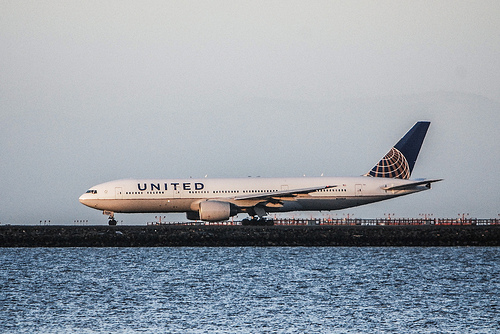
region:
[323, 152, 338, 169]
part of an ocean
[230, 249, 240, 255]
part of the sea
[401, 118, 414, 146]
edge of a plane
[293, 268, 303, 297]
part of a water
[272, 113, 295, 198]
part of a plane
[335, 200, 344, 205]
part of a plane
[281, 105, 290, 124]
part of a cloud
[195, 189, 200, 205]
part of a wheel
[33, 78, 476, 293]
plane next to the water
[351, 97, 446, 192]
tail of the plane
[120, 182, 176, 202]
windows on side of plane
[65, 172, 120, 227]
nose of the plane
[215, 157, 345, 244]
wing of the plane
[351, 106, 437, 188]
design on the tail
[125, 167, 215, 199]
word on side of plane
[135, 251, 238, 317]
water near the plane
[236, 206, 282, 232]
wheels on bottom of plane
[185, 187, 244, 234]
engine on side of plane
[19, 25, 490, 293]
this is a plane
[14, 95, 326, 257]
this is a runway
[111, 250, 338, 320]
this is a body of water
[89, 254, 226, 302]
the water is calm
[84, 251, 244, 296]
the water is blue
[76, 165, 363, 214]
this is a passenger plane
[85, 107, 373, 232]
this is a commercial flight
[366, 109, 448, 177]
the tail is blue and yellow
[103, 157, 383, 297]
the plane is gold and white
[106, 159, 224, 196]
the writing says "united"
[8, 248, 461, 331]
water in front of the airplane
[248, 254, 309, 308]
small waves in the water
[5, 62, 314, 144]
clouds in the sky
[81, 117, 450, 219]
an airplane on the runway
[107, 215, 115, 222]
a wheel on the airplane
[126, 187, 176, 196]
windows on the airplane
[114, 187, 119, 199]
a door on the airplane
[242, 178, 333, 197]
a wing on the airplane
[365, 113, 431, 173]
the tail wing on the plane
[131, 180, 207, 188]
writing on the airplane